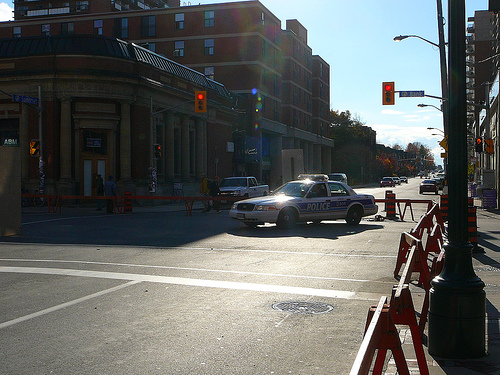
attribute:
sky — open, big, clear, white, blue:
[168, 0, 486, 149]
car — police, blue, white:
[223, 169, 386, 241]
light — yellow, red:
[193, 86, 210, 119]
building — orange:
[10, 6, 334, 200]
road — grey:
[0, 170, 446, 375]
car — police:
[229, 180, 389, 256]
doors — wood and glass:
[73, 142, 171, 218]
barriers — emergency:
[353, 227, 449, 372]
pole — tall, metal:
[426, 1, 484, 321]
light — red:
[370, 80, 414, 119]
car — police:
[252, 147, 372, 258]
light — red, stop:
[364, 70, 407, 126]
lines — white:
[137, 275, 239, 321]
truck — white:
[212, 172, 260, 212]